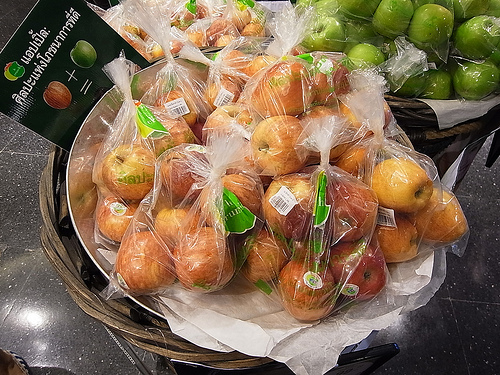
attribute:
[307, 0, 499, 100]
apple — in the picture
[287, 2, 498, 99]
apples — red, green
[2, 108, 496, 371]
floor — marble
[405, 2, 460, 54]
toilet — in the picture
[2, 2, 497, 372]
table — clean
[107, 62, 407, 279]
apples — in the picture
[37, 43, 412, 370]
basket — in the picture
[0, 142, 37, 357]
table — shiny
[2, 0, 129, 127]
book — in the picture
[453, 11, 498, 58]
green apple — bright green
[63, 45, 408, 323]
tray — in the picture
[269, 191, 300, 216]
tag — white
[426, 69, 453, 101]
apple — in the picture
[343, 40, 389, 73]
apple — in the picture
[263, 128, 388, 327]
bag — plastic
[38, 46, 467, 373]
apples basket — in the picture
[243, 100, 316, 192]
apple — in the picture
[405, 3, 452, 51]
apple — bright green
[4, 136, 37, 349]
table — black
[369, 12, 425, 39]
apple — in the picture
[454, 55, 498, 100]
apple — in the picture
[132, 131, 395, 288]
fruits — green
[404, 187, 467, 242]
apple — in the picture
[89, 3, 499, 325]
fruit — being sold